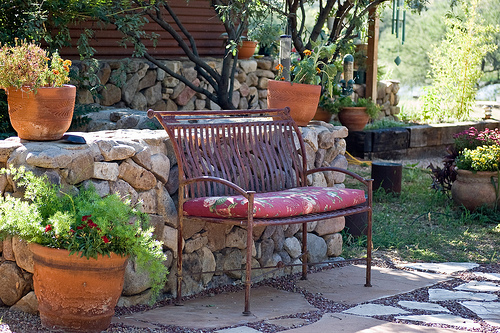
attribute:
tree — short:
[418, 1, 498, 123]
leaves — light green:
[477, 21, 498, 35]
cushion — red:
[185, 173, 367, 220]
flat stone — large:
[297, 262, 454, 303]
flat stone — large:
[116, 282, 325, 329]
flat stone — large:
[398, 297, 448, 313]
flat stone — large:
[427, 285, 498, 302]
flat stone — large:
[279, 308, 464, 331]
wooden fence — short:
[346, 119, 497, 159]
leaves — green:
[115, 1, 146, 79]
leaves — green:
[59, 25, 103, 112]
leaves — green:
[1, 0, 51, 52]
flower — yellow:
[302, 51, 312, 60]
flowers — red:
[39, 210, 114, 252]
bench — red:
[143, 75, 404, 296]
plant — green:
[433, 134, 496, 214]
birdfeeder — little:
[278, 34, 294, 84]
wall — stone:
[7, 129, 355, 305]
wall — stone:
[112, 53, 228, 110]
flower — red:
[26, 215, 161, 275]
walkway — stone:
[111, 258, 498, 329]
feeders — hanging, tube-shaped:
[273, 12, 385, 125]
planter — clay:
[445, 163, 498, 213]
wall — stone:
[0, 126, 347, 296]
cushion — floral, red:
[208, 195, 338, 207]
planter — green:
[35, 223, 130, 330]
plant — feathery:
[5, 161, 172, 276]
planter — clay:
[266, 78, 321, 128]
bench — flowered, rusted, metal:
[147, 107, 372, 317]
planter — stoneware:
[449, 168, 499, 222]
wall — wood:
[39, 0, 235, 59]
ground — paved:
[0, 165, 498, 331]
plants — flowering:
[23, 175, 130, 326]